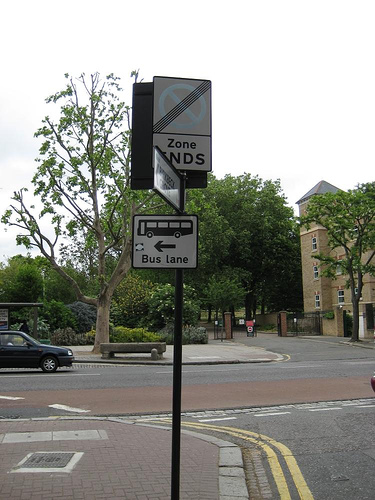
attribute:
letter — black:
[140, 250, 148, 263]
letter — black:
[194, 150, 205, 165]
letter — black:
[177, 135, 189, 154]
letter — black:
[168, 151, 181, 167]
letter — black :
[167, 135, 202, 163]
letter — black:
[165, 134, 177, 150]